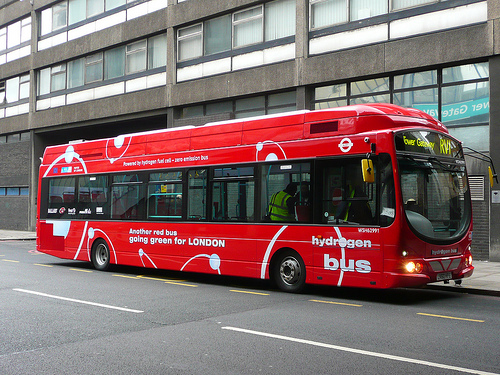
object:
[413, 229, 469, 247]
curved bottom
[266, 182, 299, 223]
man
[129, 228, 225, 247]
marketing slogan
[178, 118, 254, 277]
public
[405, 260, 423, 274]
bus headlight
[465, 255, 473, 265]
bus headlight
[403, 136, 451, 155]
electric display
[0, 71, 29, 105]
window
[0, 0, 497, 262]
building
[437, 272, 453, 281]
license plate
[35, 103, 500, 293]
bus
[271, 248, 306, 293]
front tire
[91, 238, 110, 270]
rear tire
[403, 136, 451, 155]
bus route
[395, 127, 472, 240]
windshield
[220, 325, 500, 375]
stripe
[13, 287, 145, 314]
stripe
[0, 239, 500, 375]
asphalt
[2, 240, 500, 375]
road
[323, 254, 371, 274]
word bus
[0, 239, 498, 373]
street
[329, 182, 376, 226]
person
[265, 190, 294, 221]
vest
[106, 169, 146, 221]
window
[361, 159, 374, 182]
mirror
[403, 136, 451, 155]
head sign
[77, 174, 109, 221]
window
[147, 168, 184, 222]
window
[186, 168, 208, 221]
window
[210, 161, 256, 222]
window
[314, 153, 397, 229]
window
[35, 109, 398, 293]
side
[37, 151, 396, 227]
window row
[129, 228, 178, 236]
words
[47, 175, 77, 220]
window